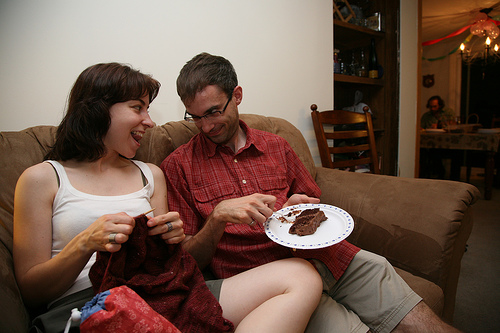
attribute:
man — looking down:
[161, 52, 462, 331]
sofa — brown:
[3, 114, 479, 330]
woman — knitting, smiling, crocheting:
[14, 63, 323, 329]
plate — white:
[264, 203, 355, 250]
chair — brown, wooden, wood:
[309, 100, 434, 219]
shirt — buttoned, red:
[160, 123, 361, 291]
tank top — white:
[38, 159, 152, 279]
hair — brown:
[53, 64, 113, 166]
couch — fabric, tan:
[3, 115, 486, 331]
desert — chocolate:
[298, 216, 314, 233]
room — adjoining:
[422, 1, 496, 197]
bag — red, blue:
[67, 285, 183, 332]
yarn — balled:
[97, 244, 112, 293]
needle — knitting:
[79, 203, 157, 252]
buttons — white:
[231, 155, 248, 189]